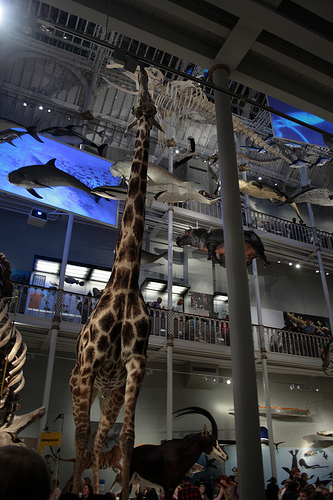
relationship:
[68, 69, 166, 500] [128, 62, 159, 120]
giraffe has head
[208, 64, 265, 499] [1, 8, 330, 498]
pillar in museum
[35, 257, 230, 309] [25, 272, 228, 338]
lights are over display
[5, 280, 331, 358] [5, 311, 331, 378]
railing over walkway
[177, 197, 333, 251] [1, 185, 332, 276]
railing over walkway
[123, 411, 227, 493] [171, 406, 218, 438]
animal has horns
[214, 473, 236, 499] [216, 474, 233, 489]
woman has hair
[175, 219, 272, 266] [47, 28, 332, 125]
hippo hangs from ceiling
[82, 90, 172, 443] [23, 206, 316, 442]
giraffe in museum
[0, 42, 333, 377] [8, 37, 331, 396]
balconies in museum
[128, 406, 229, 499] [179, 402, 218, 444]
animal has horns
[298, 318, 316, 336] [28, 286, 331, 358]
person on balcony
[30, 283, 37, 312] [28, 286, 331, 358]
person on balcony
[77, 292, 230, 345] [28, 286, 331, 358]
people on balcony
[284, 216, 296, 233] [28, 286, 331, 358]
person on balcony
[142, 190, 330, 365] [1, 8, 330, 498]
balconies in museum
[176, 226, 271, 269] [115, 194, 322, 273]
hippo hanging from walkway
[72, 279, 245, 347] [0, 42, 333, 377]
people on balconies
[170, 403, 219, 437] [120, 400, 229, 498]
horns of animal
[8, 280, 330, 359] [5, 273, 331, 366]
railing on second floor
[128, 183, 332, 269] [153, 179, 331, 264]
railing on third floor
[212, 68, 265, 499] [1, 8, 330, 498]
pillar in museum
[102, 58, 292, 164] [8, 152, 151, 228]
bones from animal